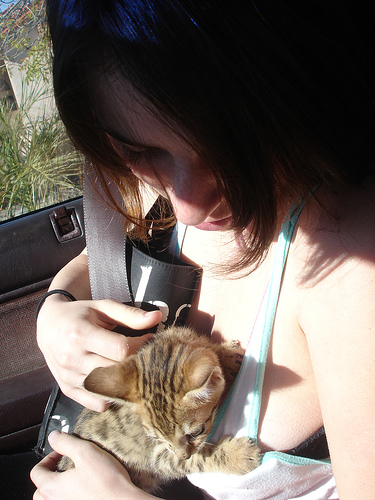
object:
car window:
[1, 1, 82, 221]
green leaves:
[24, 58, 46, 84]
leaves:
[19, 79, 25, 129]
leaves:
[6, 102, 16, 126]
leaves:
[29, 115, 42, 167]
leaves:
[6, 173, 19, 213]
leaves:
[10, 32, 30, 52]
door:
[1, 188, 132, 476]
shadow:
[313, 219, 355, 267]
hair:
[50, 2, 365, 280]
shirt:
[164, 221, 340, 500]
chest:
[146, 246, 320, 453]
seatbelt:
[81, 147, 133, 302]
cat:
[53, 325, 262, 496]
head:
[83, 326, 226, 460]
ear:
[180, 367, 223, 408]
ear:
[82, 358, 141, 403]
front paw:
[216, 435, 263, 477]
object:
[122, 238, 198, 334]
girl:
[30, 5, 374, 497]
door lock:
[47, 203, 85, 243]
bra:
[276, 423, 330, 461]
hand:
[35, 298, 163, 413]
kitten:
[44, 325, 262, 491]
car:
[3, 1, 372, 497]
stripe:
[161, 338, 173, 429]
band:
[36, 289, 79, 322]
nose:
[160, 159, 228, 230]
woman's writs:
[35, 281, 73, 364]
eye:
[110, 143, 173, 168]